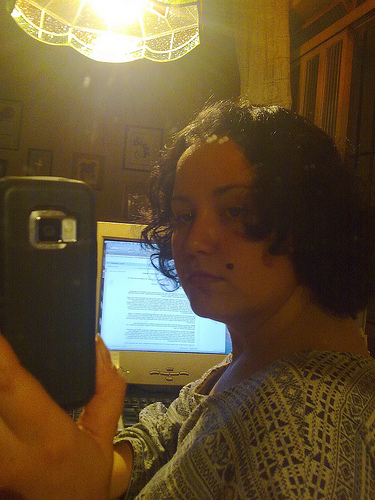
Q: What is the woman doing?
A: Taking selfie.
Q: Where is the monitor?
A: Behind the woman.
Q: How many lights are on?
A: One.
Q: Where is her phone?
A: In her hand.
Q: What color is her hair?
A: Black.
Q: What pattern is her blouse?
A: Batik.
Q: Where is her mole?
A: Left cheek.